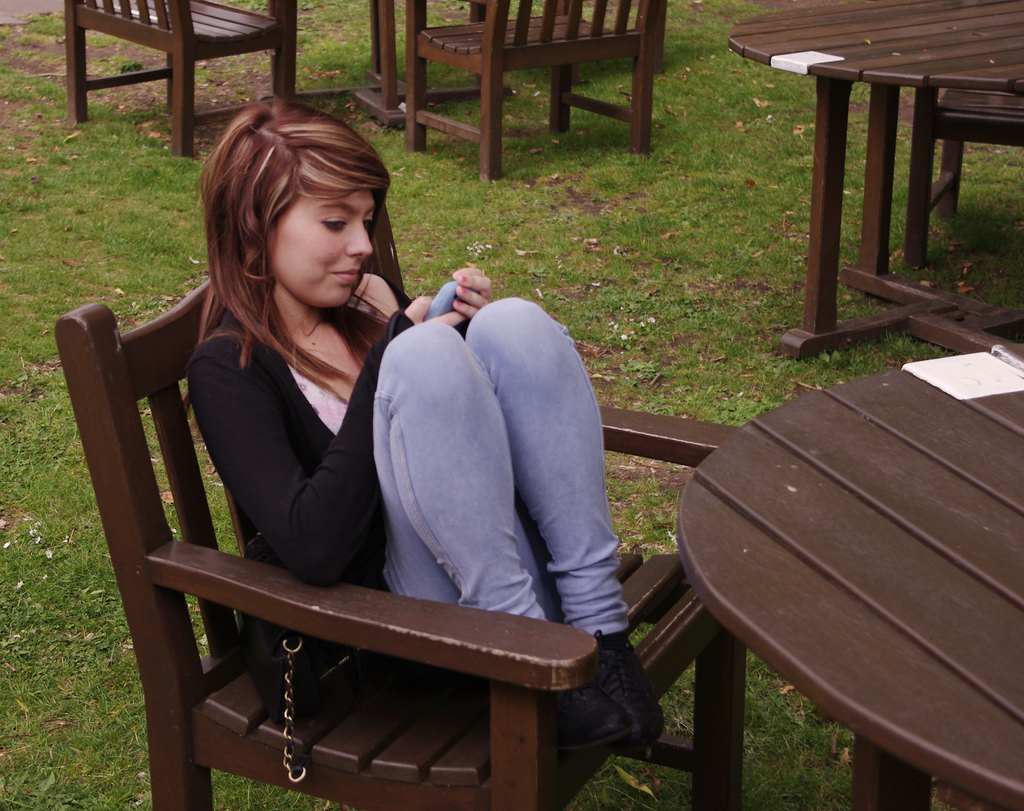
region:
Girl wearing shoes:
[510, 620, 672, 766]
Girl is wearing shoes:
[509, 595, 683, 767]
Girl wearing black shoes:
[494, 607, 690, 769]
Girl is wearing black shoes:
[520, 611, 666, 758]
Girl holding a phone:
[405, 263, 483, 336]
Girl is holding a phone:
[411, 260, 491, 334]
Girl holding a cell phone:
[411, 263, 482, 344]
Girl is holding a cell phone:
[408, 258, 491, 347]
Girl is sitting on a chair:
[46, 87, 771, 808]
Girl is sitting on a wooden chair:
[49, 87, 783, 808]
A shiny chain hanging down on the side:
[283, 662, 290, 752]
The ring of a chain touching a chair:
[289, 762, 306, 779]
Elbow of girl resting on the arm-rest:
[294, 556, 333, 586]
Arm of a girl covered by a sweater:
[233, 417, 266, 501]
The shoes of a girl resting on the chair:
[566, 705, 662, 743]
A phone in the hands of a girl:
[435, 292, 448, 306]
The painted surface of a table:
[814, 439, 1020, 576]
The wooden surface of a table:
[783, 495, 1019, 639]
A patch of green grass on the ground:
[35, 210, 188, 275]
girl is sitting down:
[193, 107, 668, 746]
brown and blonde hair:
[191, 101, 406, 393]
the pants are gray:
[374, 296, 632, 639]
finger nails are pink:
[454, 273, 470, 313]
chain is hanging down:
[272, 634, 304, 787]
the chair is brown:
[61, 259, 752, 807]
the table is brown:
[675, 343, 1021, 808]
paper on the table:
[904, 344, 1022, 396]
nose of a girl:
[348, 214, 371, 257]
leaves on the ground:
[529, 175, 692, 287]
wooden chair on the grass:
[35, 236, 760, 802]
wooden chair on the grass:
[57, 0, 314, 173]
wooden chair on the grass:
[399, 0, 675, 185]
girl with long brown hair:
[169, 88, 392, 409]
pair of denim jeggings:
[378, 301, 629, 659]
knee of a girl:
[396, 329, 466, 434]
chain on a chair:
[264, 638, 332, 784]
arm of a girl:
[189, 305, 401, 587]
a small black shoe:
[539, 667, 631, 765]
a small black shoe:
[583, 611, 678, 764]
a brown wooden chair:
[46, 235, 773, 792]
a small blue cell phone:
[401, 276, 460, 315]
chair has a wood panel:
[144, 379, 236, 642]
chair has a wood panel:
[230, 489, 256, 567]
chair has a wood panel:
[56, 306, 212, 807]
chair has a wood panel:
[154, 545, 598, 691]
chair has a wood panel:
[801, 77, 844, 337]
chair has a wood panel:
[600, 401, 740, 466]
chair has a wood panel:
[616, 549, 678, 623]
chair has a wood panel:
[634, 589, 710, 694]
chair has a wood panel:
[428, 704, 499, 787]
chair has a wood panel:
[375, 694, 477, 777]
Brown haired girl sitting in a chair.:
[188, 98, 667, 750]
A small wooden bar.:
[154, 373, 250, 662]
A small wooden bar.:
[148, 535, 607, 682]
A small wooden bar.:
[615, 533, 685, 623]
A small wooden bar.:
[607, 545, 643, 578]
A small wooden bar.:
[518, 4, 534, 50]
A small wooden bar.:
[544, 0, 563, 49]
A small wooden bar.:
[568, 7, 581, 47]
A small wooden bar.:
[596, 0, 615, 38]